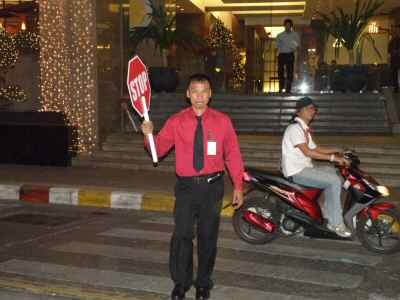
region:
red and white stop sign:
[126, 57, 154, 117]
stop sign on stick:
[126, 55, 158, 164]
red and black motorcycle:
[246, 159, 398, 255]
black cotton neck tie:
[195, 117, 205, 171]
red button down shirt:
[148, 109, 246, 190]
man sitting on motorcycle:
[285, 95, 354, 237]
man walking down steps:
[276, 20, 300, 90]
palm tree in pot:
[318, 1, 376, 67]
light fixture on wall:
[368, 21, 378, 33]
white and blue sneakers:
[328, 223, 350, 237]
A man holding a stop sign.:
[112, 51, 242, 292]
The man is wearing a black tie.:
[183, 115, 213, 176]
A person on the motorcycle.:
[255, 110, 391, 258]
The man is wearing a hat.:
[287, 91, 317, 106]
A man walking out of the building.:
[256, 12, 318, 102]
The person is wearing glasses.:
[292, 99, 325, 115]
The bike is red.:
[251, 152, 384, 265]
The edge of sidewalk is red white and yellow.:
[42, 185, 150, 215]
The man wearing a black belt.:
[166, 166, 233, 184]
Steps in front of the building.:
[230, 89, 398, 137]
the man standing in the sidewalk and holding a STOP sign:
[126, 55, 244, 299]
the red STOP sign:
[127, 55, 150, 115]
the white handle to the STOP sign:
[140, 96, 157, 162]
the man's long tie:
[193, 116, 204, 170]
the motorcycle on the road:
[232, 152, 398, 254]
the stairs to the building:
[71, 77, 399, 187]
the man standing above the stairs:
[273, 17, 300, 93]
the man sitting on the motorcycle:
[280, 97, 350, 237]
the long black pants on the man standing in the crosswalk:
[170, 177, 224, 287]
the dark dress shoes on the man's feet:
[170, 284, 209, 298]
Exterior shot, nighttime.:
[0, 2, 396, 292]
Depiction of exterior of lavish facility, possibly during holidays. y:
[1, 1, 393, 293]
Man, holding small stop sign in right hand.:
[124, 45, 244, 293]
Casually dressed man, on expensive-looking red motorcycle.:
[245, 92, 390, 256]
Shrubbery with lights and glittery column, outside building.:
[0, 4, 97, 160]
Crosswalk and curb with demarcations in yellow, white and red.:
[4, 156, 392, 296]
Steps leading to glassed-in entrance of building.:
[120, 0, 392, 196]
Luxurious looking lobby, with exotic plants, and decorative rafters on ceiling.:
[140, 4, 389, 93]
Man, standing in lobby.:
[269, 13, 301, 101]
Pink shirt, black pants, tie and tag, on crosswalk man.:
[160, 102, 245, 294]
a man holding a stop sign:
[94, 32, 252, 297]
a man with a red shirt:
[107, 35, 257, 288]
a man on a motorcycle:
[246, 80, 394, 274]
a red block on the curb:
[14, 165, 55, 214]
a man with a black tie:
[84, 41, 256, 298]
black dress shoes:
[151, 263, 221, 299]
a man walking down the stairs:
[256, 12, 311, 98]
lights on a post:
[21, 3, 110, 160]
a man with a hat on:
[271, 76, 329, 180]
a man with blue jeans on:
[266, 72, 362, 245]